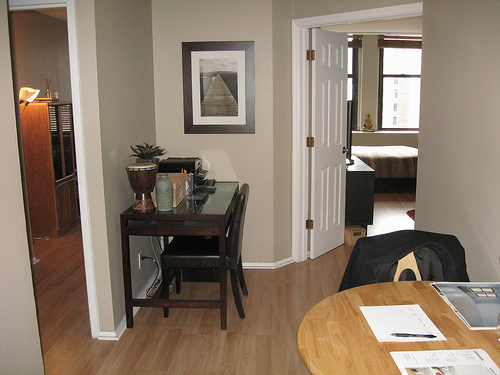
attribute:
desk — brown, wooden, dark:
[119, 143, 241, 332]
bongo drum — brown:
[123, 156, 162, 219]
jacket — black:
[336, 231, 481, 300]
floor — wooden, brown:
[133, 319, 300, 373]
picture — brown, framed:
[175, 34, 258, 140]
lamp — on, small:
[9, 85, 45, 124]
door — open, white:
[305, 26, 348, 262]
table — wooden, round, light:
[297, 281, 499, 373]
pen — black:
[389, 329, 444, 344]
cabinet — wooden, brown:
[13, 89, 82, 246]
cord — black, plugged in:
[141, 252, 170, 300]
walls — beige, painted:
[0, 1, 499, 284]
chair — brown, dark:
[161, 181, 260, 310]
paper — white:
[357, 296, 445, 347]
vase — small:
[153, 169, 179, 218]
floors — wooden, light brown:
[38, 164, 499, 373]